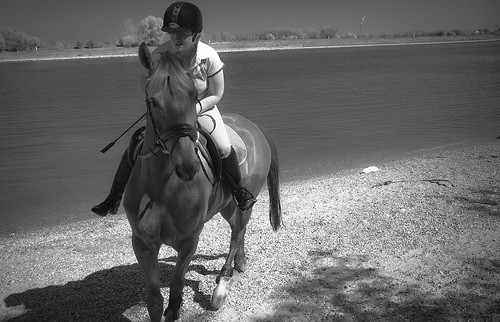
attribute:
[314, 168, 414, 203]
pebbles — white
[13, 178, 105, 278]
beach — calm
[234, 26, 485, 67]
coast line — low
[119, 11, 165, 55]
trees — small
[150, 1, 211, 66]
helmet — black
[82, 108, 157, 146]
crop — short, dark, black, long, thin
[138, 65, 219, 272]
horse — race horse, brown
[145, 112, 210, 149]
bridle — leather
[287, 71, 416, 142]
water — calm, grey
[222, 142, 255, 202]
riding boots — black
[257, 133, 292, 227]
tail — black, long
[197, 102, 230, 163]
pants — white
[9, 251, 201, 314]
shadow — black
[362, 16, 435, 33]
sky — dull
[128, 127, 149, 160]
rope — black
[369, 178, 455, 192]
branch — long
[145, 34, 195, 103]
mane — blond